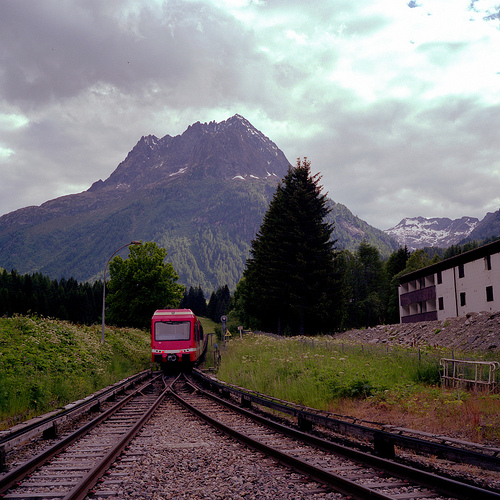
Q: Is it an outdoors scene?
A: Yes, it is outdoors.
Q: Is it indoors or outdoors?
A: It is outdoors.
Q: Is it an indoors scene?
A: No, it is outdoors.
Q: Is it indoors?
A: No, it is outdoors.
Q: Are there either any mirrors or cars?
A: No, there are no cars or mirrors.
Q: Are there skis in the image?
A: No, there are no skis.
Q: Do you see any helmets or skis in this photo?
A: No, there are no skis or helmets.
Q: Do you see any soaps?
A: No, there are no soaps.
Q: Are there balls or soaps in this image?
A: No, there are no soaps or balls.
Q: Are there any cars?
A: No, there are no cars.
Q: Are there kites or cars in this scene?
A: No, there are no cars or kites.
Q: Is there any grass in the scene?
A: Yes, there is grass.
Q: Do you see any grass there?
A: Yes, there is grass.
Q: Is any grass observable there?
A: Yes, there is grass.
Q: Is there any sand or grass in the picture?
A: Yes, there is grass.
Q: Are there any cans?
A: No, there are no cans.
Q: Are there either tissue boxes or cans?
A: No, there are no cans or tissue boxes.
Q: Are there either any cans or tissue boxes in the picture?
A: No, there are no cans or tissue boxes.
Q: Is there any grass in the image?
A: Yes, there is grass.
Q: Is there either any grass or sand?
A: Yes, there is grass.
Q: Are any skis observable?
A: No, there are no skis.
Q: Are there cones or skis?
A: No, there are no skis or cones.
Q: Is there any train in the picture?
A: Yes, there is a train.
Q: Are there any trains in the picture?
A: Yes, there is a train.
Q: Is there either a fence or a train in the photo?
A: Yes, there is a train.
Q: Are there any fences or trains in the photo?
A: Yes, there is a train.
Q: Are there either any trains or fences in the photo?
A: Yes, there is a train.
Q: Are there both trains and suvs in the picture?
A: No, there is a train but no suvs.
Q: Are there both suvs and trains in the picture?
A: No, there is a train but no suvs.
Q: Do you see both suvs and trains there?
A: No, there is a train but no suvs.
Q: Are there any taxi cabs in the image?
A: No, there are no taxi cabs.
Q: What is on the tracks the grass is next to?
A: The train is on the railroad tracks.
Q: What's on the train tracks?
A: The train is on the railroad tracks.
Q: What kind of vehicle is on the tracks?
A: The vehicle is a train.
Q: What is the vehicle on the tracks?
A: The vehicle is a train.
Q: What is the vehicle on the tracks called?
A: The vehicle is a train.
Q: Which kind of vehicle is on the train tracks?
A: The vehicle is a train.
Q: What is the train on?
A: The train is on the train tracks.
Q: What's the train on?
A: The train is on the train tracks.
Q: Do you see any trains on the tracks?
A: Yes, there is a train on the tracks.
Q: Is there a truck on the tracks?
A: No, there is a train on the tracks.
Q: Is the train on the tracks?
A: Yes, the train is on the tracks.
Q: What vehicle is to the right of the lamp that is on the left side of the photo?
A: The vehicle is a train.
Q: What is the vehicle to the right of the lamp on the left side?
A: The vehicle is a train.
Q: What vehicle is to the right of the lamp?
A: The vehicle is a train.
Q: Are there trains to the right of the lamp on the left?
A: Yes, there is a train to the right of the lamp.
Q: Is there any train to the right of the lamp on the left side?
A: Yes, there is a train to the right of the lamp.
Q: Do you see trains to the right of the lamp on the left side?
A: Yes, there is a train to the right of the lamp.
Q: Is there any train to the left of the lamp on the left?
A: No, the train is to the right of the lamp.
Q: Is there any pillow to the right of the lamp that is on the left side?
A: No, there is a train to the right of the lamp.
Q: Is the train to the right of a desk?
A: No, the train is to the right of a lamp.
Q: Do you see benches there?
A: No, there are no benches.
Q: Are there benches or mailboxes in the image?
A: No, there are no benches or mailboxes.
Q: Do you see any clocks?
A: No, there are no clocks.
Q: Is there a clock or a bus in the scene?
A: No, there are no clocks or buses.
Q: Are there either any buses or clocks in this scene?
A: No, there are no clocks or buses.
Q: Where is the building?
A: The building is on the hill.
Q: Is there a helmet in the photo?
A: No, there are no helmets.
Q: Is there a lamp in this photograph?
A: Yes, there is a lamp.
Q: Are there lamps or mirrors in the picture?
A: Yes, there is a lamp.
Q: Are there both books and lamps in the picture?
A: No, there is a lamp but no books.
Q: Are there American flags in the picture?
A: No, there are no American flags.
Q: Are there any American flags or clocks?
A: No, there are no American flags or clocks.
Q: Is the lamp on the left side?
A: Yes, the lamp is on the left of the image.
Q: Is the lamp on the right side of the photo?
A: No, the lamp is on the left of the image.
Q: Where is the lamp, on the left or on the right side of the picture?
A: The lamp is on the left of the image.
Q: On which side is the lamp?
A: The lamp is on the left of the image.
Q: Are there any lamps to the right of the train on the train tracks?
A: No, the lamp is to the left of the train.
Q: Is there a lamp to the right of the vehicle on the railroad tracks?
A: No, the lamp is to the left of the train.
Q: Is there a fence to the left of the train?
A: No, there is a lamp to the left of the train.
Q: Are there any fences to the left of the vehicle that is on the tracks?
A: No, there is a lamp to the left of the train.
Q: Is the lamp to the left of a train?
A: Yes, the lamp is to the left of a train.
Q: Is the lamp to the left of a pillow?
A: No, the lamp is to the left of a train.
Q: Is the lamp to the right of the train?
A: No, the lamp is to the left of the train.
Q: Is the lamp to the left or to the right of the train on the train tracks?
A: The lamp is to the left of the train.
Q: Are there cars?
A: No, there are no cars.